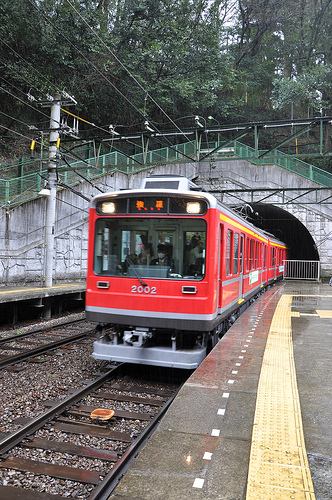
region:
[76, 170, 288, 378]
Subway is moving on the track.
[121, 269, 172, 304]
The number on the train.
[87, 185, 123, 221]
Headlight on front of the train.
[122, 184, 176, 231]
Sign with symbols on front of train.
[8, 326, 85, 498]
Train tracks with gravel underneath.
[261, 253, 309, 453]
Subway platform with yellow hazard line.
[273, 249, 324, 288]
Fence to block people from entering tunnel.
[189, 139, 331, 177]
Stair case leading to subway platform.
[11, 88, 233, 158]
Electrical wires to operate train.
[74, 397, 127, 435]
Mechanism on tracks help operate activity.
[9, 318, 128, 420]
train tracks with gravel between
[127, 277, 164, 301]
train number on front of train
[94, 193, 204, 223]
light on front of train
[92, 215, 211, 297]
front widnsheld on front of train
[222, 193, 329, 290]
train tunnel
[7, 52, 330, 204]
power lines and poles used to control train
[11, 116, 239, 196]
green metal fencing around walkway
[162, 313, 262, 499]
white dotted lines painted beside train track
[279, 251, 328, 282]
gray metal safety gate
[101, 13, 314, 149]
tall trees on hillside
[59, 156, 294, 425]
Train on the tracks.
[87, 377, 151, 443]
Item on the track.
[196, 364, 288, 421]
White marks on the side of the track.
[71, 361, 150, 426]
Rocks on the track.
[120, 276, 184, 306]
2002 written on the train.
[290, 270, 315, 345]
Water on the road.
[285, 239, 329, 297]
Fence by the tunnel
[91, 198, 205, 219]
Lights on the train.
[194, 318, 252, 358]
Wheels on the train.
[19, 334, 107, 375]
Steel rails on the track.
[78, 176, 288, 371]
a red train traveling down tracks.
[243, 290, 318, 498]
a yellow line in a train station.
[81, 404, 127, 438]
an object laying on train tracks.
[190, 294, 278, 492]
a row of white lines.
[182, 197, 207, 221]
a headlight on a train.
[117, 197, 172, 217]
a light on a train.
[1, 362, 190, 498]
train tracks in a loading area.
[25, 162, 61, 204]
a light hanging from a pole.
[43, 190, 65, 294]
a white pole near train tracks.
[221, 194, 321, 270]
a black tunnel.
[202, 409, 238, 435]
small white squares on platform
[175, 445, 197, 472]
small light shining on platform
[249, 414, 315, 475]
wide yellow lines with smudges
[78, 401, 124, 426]
small brown square on track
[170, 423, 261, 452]
lines on the platform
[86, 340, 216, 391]
gray bottom on train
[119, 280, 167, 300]
silver words on train front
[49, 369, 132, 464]
rusted brown train tracks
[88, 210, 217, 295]
large window in front of train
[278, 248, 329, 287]
large silver gate at end of train